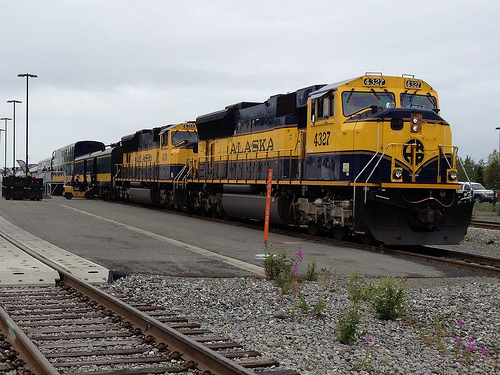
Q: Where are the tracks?
A: Under the train.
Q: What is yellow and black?
A: Train.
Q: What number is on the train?
A: 4327.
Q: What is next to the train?
A: Cement.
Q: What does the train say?
A: Alaska.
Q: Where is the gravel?
A: Next to the train.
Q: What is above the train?
A: The gray sky.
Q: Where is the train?
A: On the tracks.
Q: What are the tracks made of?
A: Metal.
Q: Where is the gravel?
A: Next to the tracks.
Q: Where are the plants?
A: On the gravel.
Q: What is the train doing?
A: Moving.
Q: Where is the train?
A: On the tracks.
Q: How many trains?
A: 1.